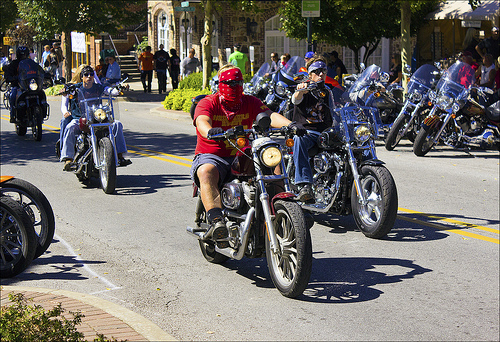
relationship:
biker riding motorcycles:
[189, 62, 297, 233] [195, 163, 317, 299]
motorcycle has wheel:
[187, 124, 319, 296] [259, 199, 311, 300]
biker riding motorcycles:
[189, 62, 297, 233] [186, 142, 402, 310]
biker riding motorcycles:
[189, 62, 297, 233] [191, 122, 406, 302]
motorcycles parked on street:
[352, 60, 484, 153] [0, 84, 498, 340]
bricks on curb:
[70, 300, 101, 339] [2, 280, 162, 340]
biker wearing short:
[189, 62, 297, 233] [187, 149, 236, 196]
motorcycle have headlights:
[187, 124, 315, 299] [81, 97, 387, 182]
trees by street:
[23, 3, 416, 44] [42, 93, 483, 325]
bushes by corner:
[172, 82, 204, 110] [150, 97, 195, 120]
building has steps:
[67, 6, 401, 78] [117, 53, 141, 83]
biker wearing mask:
[189, 60, 297, 231] [213, 60, 248, 104]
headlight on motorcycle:
[262, 146, 283, 167] [178, 116, 315, 300]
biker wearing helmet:
[58, 65, 134, 171] [80, 63, 95, 77]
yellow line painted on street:
[5, 103, 499, 250] [0, 84, 498, 340]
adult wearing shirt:
[132, 39, 156, 96] [138, 49, 158, 75]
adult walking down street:
[132, 39, 156, 96] [0, 84, 498, 340]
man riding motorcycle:
[285, 49, 341, 142] [267, 92, 403, 237]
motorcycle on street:
[267, 92, 403, 237] [0, 84, 498, 340]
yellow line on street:
[5, 103, 499, 250] [0, 84, 498, 340]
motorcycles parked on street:
[343, 50, 497, 165] [0, 84, 498, 340]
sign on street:
[300, 0, 318, 21] [0, 84, 498, 340]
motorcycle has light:
[187, 124, 315, 299] [258, 139, 288, 173]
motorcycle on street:
[187, 124, 315, 299] [0, 84, 498, 340]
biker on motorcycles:
[189, 62, 297, 233] [4, 65, 403, 295]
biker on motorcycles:
[189, 62, 297, 233] [0, 54, 420, 304]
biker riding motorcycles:
[189, 62, 297, 233] [4, 65, 403, 295]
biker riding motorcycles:
[189, 62, 297, 233] [0, 54, 420, 304]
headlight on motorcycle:
[262, 142, 283, 168] [187, 124, 315, 299]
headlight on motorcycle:
[354, 120, 370, 142] [249, 82, 398, 236]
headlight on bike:
[88, 104, 107, 122] [58, 77, 131, 195]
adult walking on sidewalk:
[135, 44, 156, 96] [107, 77, 180, 96]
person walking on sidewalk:
[148, 44, 172, 98] [107, 77, 180, 96]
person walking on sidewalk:
[165, 46, 184, 86] [107, 77, 180, 96]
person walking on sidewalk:
[216, 44, 251, 84] [107, 77, 180, 96]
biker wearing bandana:
[189, 62, 297, 233] [212, 62, 246, 103]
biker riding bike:
[58, 65, 134, 171] [58, 77, 135, 191]